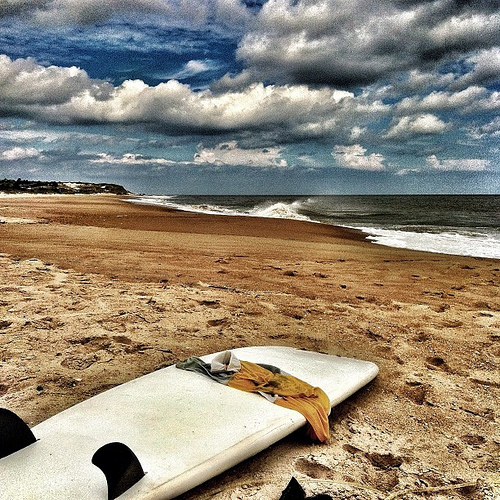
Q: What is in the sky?
A: White and gray clouds.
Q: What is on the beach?
A: A white surfboard.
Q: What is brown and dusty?
A: The sand.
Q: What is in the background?
A: A hill.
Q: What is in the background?
A: The water.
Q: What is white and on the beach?
A: The surfboard.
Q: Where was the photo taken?
A: Beach.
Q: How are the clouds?
A: Grey.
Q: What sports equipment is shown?
A: A surfboard.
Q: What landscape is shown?
A: The beach.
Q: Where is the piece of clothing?
A: On the surfboard.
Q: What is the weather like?
A: Cloudy.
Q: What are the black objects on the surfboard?
A: The fins.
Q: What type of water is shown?
A: Salt water.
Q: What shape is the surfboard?
A: Oval.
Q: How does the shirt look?
A: Wet.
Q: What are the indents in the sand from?
A: Footprints.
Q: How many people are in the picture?
A: None.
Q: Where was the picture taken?
A: Beach.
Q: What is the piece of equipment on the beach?
A: Surfboard.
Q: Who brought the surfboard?
A: Surfer.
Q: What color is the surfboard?
A: White.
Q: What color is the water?
A: Black.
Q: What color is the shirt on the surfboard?
A: Yellow.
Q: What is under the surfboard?
A: Sand.